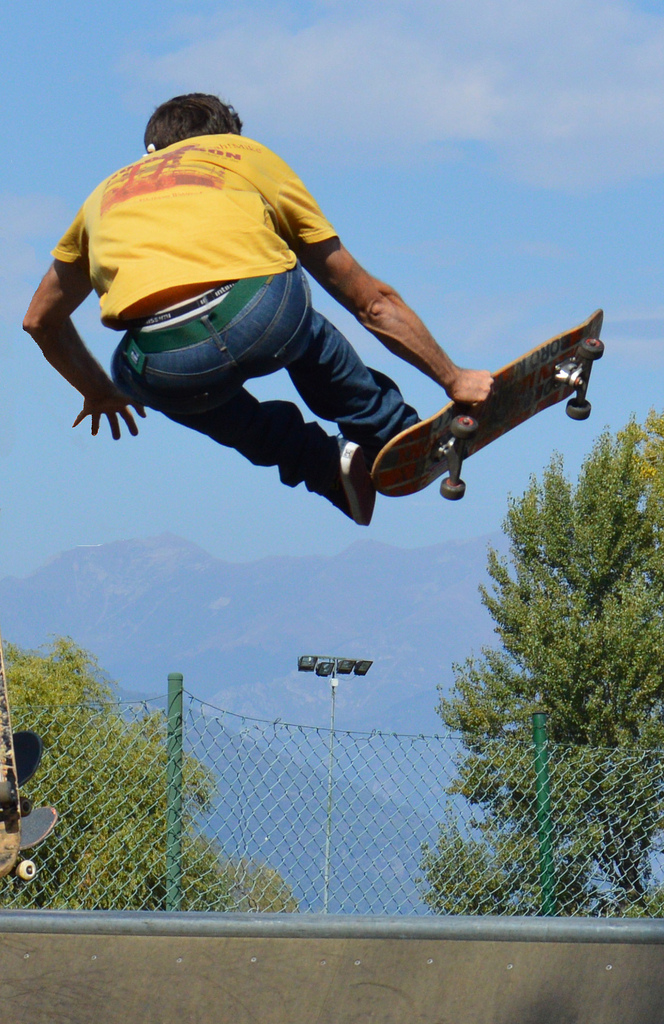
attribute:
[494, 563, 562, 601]
leaves — green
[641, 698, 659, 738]
leaves — green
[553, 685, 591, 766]
leaves — green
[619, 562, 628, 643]
leaves — green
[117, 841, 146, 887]
leaves — green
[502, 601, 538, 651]
leaves — green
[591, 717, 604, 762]
leaves — green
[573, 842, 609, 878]
leaves — green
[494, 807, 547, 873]
leaves — green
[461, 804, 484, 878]
leaves — green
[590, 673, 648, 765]
leaves — green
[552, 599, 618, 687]
leaves — green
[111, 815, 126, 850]
leaves — green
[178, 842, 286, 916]
leaves — green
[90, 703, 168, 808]
leaves — green